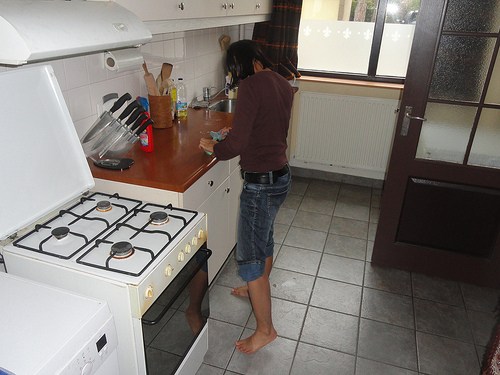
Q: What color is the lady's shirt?
A: Burgundy.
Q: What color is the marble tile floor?
A: Grey.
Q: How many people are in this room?
A: One.